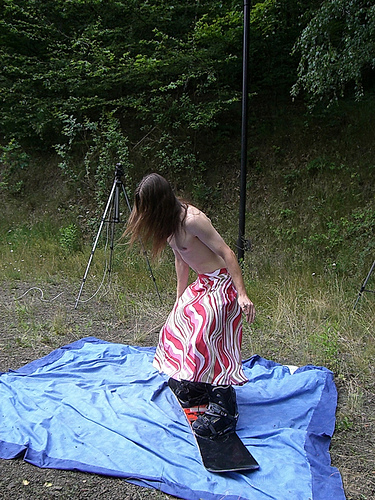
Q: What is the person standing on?
A: Blue blanket.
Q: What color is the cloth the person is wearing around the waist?
A: Red and white.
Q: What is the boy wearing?
A: Long red and white skirt.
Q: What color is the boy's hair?
A: Brown.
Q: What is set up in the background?
A: A tripod.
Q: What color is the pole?
A: Black.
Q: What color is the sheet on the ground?
A: Blue.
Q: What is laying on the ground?
A: A sheet.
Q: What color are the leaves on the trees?
A: Green.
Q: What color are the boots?
A: Black.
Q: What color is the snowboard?
A: Black.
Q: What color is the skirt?
A: Pink and white.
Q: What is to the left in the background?
A: A tripod and camera.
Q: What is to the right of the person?
A: A pole.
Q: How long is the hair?
A: Past the shoulders.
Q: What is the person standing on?
A: A ski board.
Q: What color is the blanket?
A: Blue.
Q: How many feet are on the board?
A: 2.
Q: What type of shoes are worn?
A: Boots.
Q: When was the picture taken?
A: During the daylight.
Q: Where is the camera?
A: On the tripod.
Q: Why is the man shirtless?
A: It's hot.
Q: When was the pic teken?
A: During the day.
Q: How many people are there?
A: 1.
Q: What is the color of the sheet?
A: Blue.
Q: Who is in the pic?
A: A man.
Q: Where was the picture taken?
A: In a field.